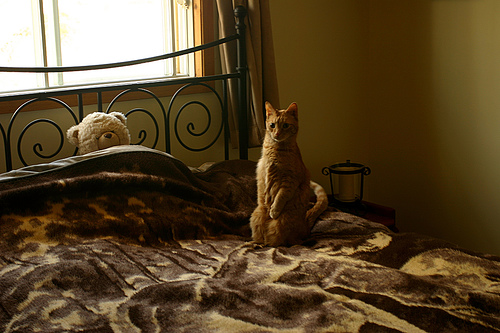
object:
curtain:
[218, 0, 283, 150]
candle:
[339, 159, 355, 200]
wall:
[325, 34, 465, 123]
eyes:
[269, 123, 289, 128]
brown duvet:
[0, 142, 497, 331]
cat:
[249, 101, 328, 247]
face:
[88, 124, 123, 150]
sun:
[65, 12, 160, 50]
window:
[0, 0, 214, 114]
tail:
[307, 180, 328, 227]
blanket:
[48, 190, 308, 317]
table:
[327, 194, 396, 226]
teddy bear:
[66, 111, 130, 154]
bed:
[0, 31, 497, 331]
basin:
[321, 159, 371, 209]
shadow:
[335, 3, 447, 246]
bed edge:
[0, 72, 257, 192]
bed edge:
[328, 197, 497, 259]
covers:
[0, 171, 500, 332]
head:
[265, 101, 299, 141]